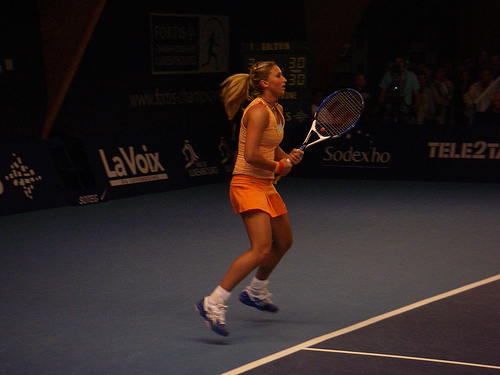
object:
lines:
[305, 275, 500, 348]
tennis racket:
[275, 88, 366, 178]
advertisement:
[92, 144, 170, 186]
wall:
[0, 114, 234, 219]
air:
[0, 0, 500, 374]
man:
[375, 54, 422, 124]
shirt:
[378, 70, 423, 116]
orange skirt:
[227, 173, 292, 220]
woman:
[191, 57, 305, 339]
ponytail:
[217, 72, 248, 122]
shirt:
[230, 98, 288, 181]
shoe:
[193, 295, 234, 338]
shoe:
[234, 287, 279, 315]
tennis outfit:
[227, 97, 290, 218]